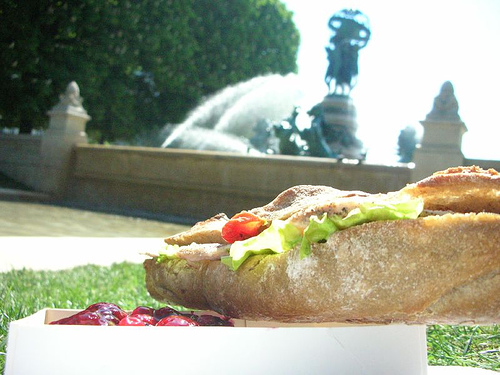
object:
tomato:
[221, 211, 264, 243]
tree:
[1, 0, 298, 149]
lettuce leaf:
[221, 193, 424, 270]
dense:
[4, 4, 271, 104]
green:
[8, 3, 237, 68]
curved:
[63, 139, 413, 189]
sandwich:
[142, 164, 500, 326]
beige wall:
[4, 138, 406, 227]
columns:
[0, 79, 500, 221]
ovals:
[162, 73, 402, 154]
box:
[3, 307, 427, 375]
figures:
[323, 7, 371, 96]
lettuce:
[218, 197, 423, 272]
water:
[197, 82, 255, 150]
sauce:
[50, 301, 229, 326]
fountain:
[162, 69, 390, 153]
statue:
[323, 8, 370, 95]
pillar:
[306, 94, 367, 161]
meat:
[178, 242, 230, 262]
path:
[0, 233, 174, 272]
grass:
[0, 191, 199, 236]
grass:
[0, 261, 497, 371]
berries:
[49, 310, 107, 325]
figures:
[395, 126, 418, 163]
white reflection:
[7, 197, 137, 271]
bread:
[142, 166, 500, 324]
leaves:
[6, 1, 299, 121]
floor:
[2, 178, 202, 238]